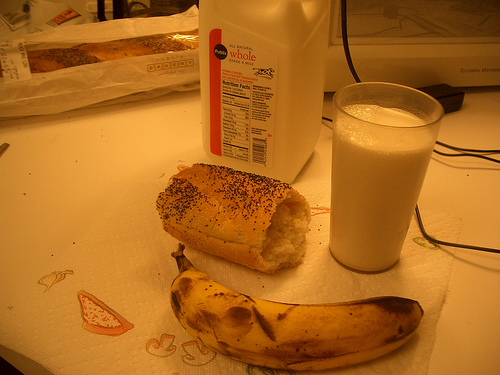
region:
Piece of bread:
[157, 161, 311, 276]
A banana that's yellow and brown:
[164, 242, 422, 371]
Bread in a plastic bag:
[0, 5, 200, 117]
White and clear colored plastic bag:
[1, 4, 198, 119]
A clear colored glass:
[328, 80, 443, 275]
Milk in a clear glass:
[331, 103, 435, 275]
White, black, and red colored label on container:
[209, 27, 279, 168]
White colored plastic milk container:
[198, 0, 327, 183]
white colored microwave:
[325, 1, 499, 92]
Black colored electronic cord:
[322, 82, 499, 257]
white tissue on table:
[351, 224, 495, 309]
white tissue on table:
[364, 260, 492, 365]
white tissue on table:
[372, 257, 472, 321]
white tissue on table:
[397, 241, 451, 321]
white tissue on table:
[415, 284, 475, 345]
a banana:
[163, 244, 426, 368]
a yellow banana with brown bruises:
[160, 245, 440, 373]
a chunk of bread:
[149, 150, 315, 272]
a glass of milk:
[327, 75, 444, 278]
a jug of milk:
[195, 0, 331, 190]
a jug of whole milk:
[196, 0, 335, 182]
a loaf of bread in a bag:
[0, 10, 229, 123]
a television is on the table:
[328, 0, 498, 110]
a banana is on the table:
[155, 242, 430, 373]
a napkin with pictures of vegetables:
[26, 185, 462, 371]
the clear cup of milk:
[329, 77, 442, 269]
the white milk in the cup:
[329, 119, 429, 274]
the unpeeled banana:
[161, 244, 422, 364]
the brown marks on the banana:
[178, 275, 408, 346]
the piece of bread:
[163, 157, 308, 258]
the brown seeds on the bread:
[176, 168, 265, 221]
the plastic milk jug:
[198, 7, 326, 176]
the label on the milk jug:
[206, 27, 275, 161]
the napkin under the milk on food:
[21, 172, 460, 373]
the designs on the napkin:
[39, 270, 205, 365]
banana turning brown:
[159, 243, 425, 368]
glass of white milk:
[325, 77, 445, 275]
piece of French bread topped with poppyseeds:
[152, 158, 314, 276]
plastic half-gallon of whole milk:
[194, 0, 334, 185]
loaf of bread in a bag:
[2, 4, 212, 119]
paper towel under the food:
[8, 226, 448, 373]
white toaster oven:
[298, 0, 496, 93]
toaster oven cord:
[325, 0, 496, 257]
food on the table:
[38, 0, 471, 373]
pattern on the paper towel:
[34, 263, 219, 367]